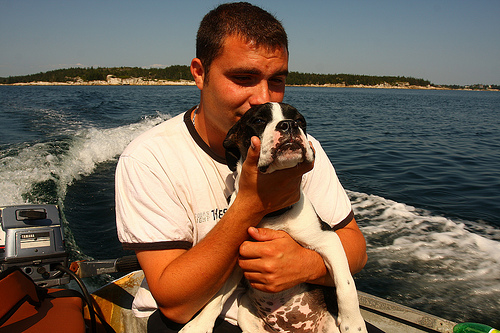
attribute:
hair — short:
[193, 2, 290, 84]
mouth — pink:
[262, 130, 331, 175]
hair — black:
[186, 1, 299, 64]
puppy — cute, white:
[177, 104, 376, 332]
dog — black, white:
[170, 92, 390, 331]